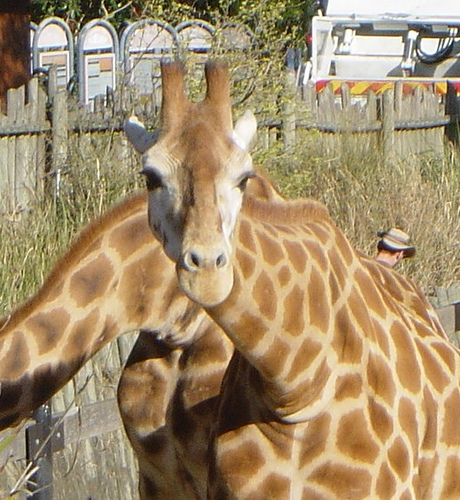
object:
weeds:
[364, 145, 451, 274]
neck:
[236, 208, 408, 392]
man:
[372, 224, 417, 270]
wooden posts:
[6, 83, 28, 204]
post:
[50, 89, 73, 210]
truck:
[307, 0, 460, 104]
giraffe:
[0, 173, 311, 499]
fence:
[1, 76, 457, 214]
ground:
[0, 151, 460, 499]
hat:
[382, 226, 415, 251]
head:
[375, 228, 414, 267]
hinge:
[25, 421, 49, 458]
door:
[0, 400, 128, 498]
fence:
[0, 400, 135, 500]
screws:
[35, 437, 41, 447]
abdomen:
[114, 341, 252, 497]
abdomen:
[205, 349, 406, 498]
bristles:
[240, 194, 330, 221]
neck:
[376, 251, 395, 268]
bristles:
[0, 193, 147, 332]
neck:
[0, 187, 148, 332]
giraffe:
[126, 61, 458, 497]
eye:
[231, 174, 255, 193]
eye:
[142, 162, 167, 193]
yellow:
[351, 82, 367, 93]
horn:
[159, 60, 188, 112]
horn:
[203, 59, 230, 104]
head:
[122, 53, 259, 306]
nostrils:
[182, 250, 201, 273]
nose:
[181, 250, 225, 272]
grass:
[0, 122, 131, 311]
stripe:
[308, 74, 447, 98]